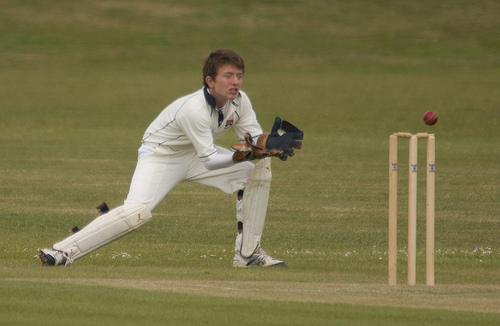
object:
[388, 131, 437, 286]
cricket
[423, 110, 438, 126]
ball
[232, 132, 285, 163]
gloves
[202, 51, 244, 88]
hair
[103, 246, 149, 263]
flowers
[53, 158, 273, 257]
shin gaurds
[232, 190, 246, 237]
straps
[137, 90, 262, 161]
shirt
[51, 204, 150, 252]
shins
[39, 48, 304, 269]
player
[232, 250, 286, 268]
cleats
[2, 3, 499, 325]
field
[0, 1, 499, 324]
grass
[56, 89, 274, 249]
uniform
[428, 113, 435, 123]
white stripe